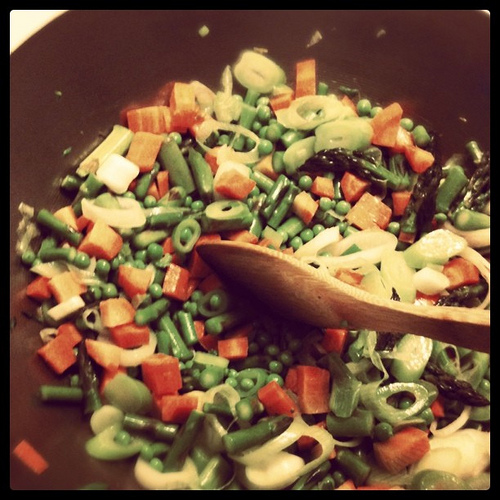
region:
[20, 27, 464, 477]
mixed vegetables on brown plate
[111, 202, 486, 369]
wooden spoon in mixed vegetables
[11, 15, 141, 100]
brown plate on white table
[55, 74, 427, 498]
vegetables include carrots, peas, green beans, onions, asparagus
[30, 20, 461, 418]
light shining on plate of food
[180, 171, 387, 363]
wooden spoon casting shadow on food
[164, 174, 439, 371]
flat wooden spoon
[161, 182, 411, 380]
wooden spoon being held on it's side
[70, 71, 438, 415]
wooden spoon mixing vegetables together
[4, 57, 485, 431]
large plate of vegetables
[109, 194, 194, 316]
green food on plate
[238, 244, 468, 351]
brown spoon in food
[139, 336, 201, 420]
red food on plate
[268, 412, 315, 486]
white food on surface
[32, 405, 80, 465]
brown surface beneath food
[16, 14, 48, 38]
white surface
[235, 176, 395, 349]
brown spoon on side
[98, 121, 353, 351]
many pieces of food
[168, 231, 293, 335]
top part of spoon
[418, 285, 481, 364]
handle of a brown spoon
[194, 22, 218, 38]
small morsel of food particle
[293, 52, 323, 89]
tiny piece of orange carrot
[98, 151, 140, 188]
white onion on the plate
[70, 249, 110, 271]
tiny green peas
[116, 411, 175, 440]
green bean with black bruise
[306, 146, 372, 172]
tiny piece of cranberry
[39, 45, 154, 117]
red plate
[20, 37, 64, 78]
edge of red plate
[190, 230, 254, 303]
edge of wooden spoon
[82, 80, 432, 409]
variety of vegetables in pot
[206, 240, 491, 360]
this is a cooking stick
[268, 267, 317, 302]
the stick is wooden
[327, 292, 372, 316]
the stick is brown in color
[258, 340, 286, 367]
these are some peas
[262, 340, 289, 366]
the peas are green in color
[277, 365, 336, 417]
these are some carrots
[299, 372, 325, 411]
the carrots are orange in color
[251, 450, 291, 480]
these are some spices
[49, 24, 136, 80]
this is a cooking container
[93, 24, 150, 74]
the container is metallic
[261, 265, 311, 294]
this is a spoon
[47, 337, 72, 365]
this is sliced carrot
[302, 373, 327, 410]
the carrot is orange in color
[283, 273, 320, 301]
the spoon is wooden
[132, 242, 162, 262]
the peas are in the middle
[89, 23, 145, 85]
this is a bowl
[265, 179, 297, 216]
this is a broccoli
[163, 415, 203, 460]
the broccoli is green in color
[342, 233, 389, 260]
this is sliced onion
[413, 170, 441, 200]
this is a polythene pper